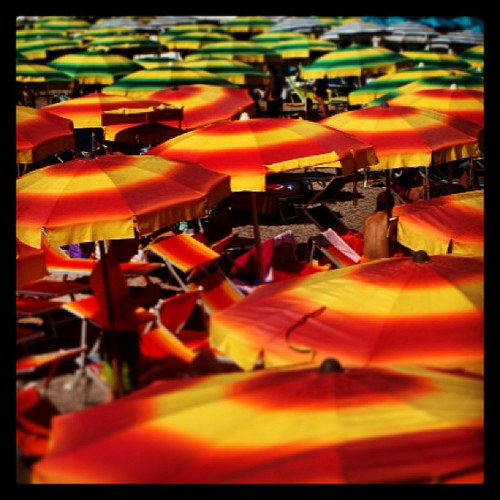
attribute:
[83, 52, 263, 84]
green/yellow stripes — green, yellow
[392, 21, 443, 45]
umbrella — blue, white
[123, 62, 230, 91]
umbrella — green, yellow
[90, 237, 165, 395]
person — standing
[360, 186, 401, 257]
person — standing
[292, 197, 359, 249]
chairs — empty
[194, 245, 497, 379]
umbrella — yellow, red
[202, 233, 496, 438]
umbrella — green, yellow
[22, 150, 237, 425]
umbrella — red , yellow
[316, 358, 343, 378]
tip — black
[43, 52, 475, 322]
umbrellas — open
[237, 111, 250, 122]
tip — round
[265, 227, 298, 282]
towel — pink, white